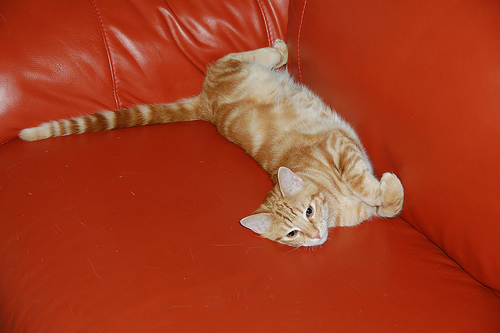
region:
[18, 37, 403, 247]
Tan and white striped kitten.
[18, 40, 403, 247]
Kitten lying on its side.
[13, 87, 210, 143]
Circular stripes on the kitten's tail.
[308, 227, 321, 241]
Kitten with a pink nose.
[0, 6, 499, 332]
Kitten lying on a red leather sofa.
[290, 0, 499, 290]
The back portion of the red sofa.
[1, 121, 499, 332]
Cushion of a red sofa.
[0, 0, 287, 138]
Arm rest of a red leather sofa.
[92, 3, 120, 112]
Stiching on the sofa arm rest.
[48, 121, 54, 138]
orange stripe on cat's tail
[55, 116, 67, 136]
orange stripe on cat's tail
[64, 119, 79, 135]
orange stripe on cat's tail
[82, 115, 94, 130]
orange stripe on cat's tail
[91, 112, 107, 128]
orange stripe on cat's tail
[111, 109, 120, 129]
orange stripe on cat's tail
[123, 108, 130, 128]
orange stripe on cat's tail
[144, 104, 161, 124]
orange stripe on cat's tail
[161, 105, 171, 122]
orange stripe on cat's tail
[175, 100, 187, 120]
orange stripe on cat's tail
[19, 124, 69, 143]
the cats tail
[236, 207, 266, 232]
the cats ear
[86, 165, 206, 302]
the couch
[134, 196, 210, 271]
the couch is red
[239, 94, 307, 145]
the cat is orange and white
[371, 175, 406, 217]
the paws of the cat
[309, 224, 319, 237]
cats nose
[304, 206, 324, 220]
the cats left eye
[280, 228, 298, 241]
right eye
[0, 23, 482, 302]
a cat laying on a couch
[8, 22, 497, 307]
cat laying on orange couch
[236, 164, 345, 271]
the head of a cat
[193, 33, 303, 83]
the hind feet of cat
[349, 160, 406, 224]
the front paws on cat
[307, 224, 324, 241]
the nose on a cat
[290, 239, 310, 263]
the white whiskers on cat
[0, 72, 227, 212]
a long tail of cat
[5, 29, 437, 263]
a tabby colored cat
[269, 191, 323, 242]
a cat with eyes open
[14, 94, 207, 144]
a tail of a cat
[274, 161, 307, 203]
an ear of a cat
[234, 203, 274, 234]
an ear of a cat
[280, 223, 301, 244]
the eye of a cat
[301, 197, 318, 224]
the eye of a cat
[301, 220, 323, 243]
the nose of a cat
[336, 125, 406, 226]
the fron legs of a cat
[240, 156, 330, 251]
a head of a cat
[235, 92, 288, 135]
the fur of a cat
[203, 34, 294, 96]
the hind legs of a cat